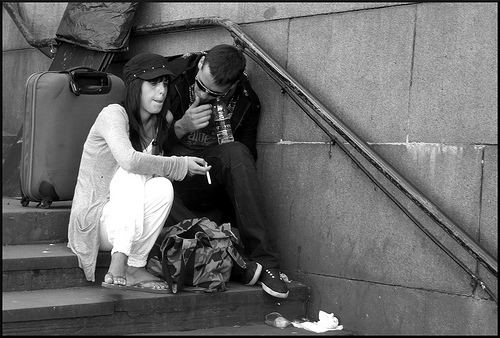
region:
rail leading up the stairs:
[287, 83, 444, 195]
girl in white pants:
[91, 44, 185, 298]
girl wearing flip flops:
[101, 268, 186, 315]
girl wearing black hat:
[114, 57, 170, 118]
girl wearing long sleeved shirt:
[76, 100, 193, 276]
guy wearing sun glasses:
[187, 55, 239, 102]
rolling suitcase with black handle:
[22, 55, 112, 206]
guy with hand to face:
[170, 67, 256, 165]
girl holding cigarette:
[112, 66, 222, 207]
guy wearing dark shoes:
[239, 239, 344, 318]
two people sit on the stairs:
[63, 47, 294, 298]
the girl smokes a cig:
[204, 162, 212, 182]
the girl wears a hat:
[126, 55, 173, 80]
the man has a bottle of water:
[213, 99, 234, 140]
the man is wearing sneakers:
[231, 262, 288, 300]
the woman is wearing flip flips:
[103, 255, 168, 293]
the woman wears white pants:
[101, 167, 173, 268]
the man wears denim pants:
[207, 143, 280, 268]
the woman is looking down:
[142, 78, 169, 110]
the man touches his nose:
[203, 92, 208, 100]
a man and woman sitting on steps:
[62, 26, 304, 312]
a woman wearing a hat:
[115, 49, 193, 154]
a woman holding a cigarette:
[97, 56, 219, 209]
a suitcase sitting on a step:
[12, 55, 132, 230]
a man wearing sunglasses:
[170, 20, 271, 195]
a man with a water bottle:
[167, 35, 255, 186]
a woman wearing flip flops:
[96, 213, 186, 314]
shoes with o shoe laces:
[226, 243, 306, 310]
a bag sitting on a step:
[115, 192, 298, 304]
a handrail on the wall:
[155, 11, 495, 301]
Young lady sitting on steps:
[66, 50, 212, 293]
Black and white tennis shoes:
[225, 240, 296, 300]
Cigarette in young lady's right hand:
[200, 155, 215, 181]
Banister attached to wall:
[30, 12, 495, 317]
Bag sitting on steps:
[155, 220, 246, 290]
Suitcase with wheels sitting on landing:
[20, 62, 127, 207]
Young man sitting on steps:
[147, 40, 310, 295]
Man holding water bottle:
[160, 45, 293, 295]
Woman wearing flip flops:
[60, 48, 205, 291]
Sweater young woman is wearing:
[54, 53, 191, 278]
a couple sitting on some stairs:
[84, 35, 289, 288]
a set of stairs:
[3, 176, 290, 336]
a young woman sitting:
[76, 45, 188, 280]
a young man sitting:
[149, 30, 313, 296]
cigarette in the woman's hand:
[196, 159, 224, 186]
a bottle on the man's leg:
[203, 100, 254, 150]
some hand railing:
[24, 7, 499, 279]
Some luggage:
[2, 22, 132, 205]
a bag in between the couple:
[153, 207, 243, 279]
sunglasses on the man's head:
[197, 60, 239, 104]